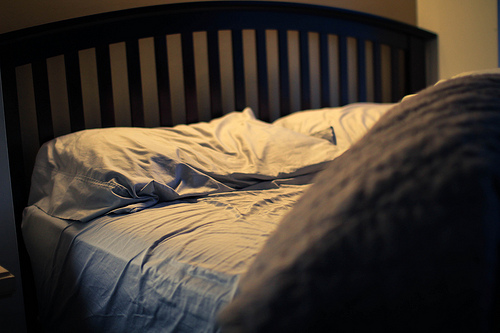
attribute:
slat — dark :
[250, 27, 275, 119]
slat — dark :
[108, 42, 133, 126]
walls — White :
[4, 1, 499, 105]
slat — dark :
[82, 35, 132, 117]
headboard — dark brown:
[85, 9, 372, 101]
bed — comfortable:
[2, 2, 468, 332]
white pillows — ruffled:
[66, 114, 225, 224]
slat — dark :
[178, 32, 198, 124]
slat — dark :
[274, 22, 292, 118]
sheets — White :
[108, 176, 263, 315]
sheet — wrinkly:
[32, 172, 255, 332]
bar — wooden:
[206, 25, 226, 126]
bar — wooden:
[148, 33, 178, 126]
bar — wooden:
[178, 27, 202, 119]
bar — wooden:
[293, 33, 315, 111]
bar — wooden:
[125, 34, 148, 125]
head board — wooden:
[2, 0, 440, 192]